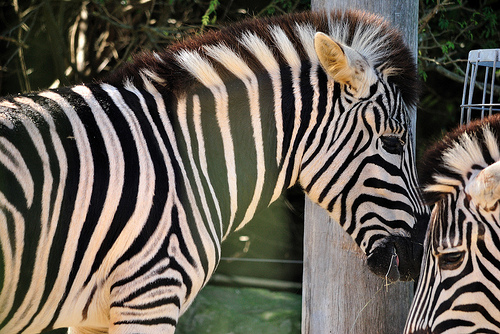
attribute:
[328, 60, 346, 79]
fur — yellow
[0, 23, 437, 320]
zebra — black, white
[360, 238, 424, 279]
mouth — black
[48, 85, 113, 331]
stripe — black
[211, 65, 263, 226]
stipe — black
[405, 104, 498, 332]
zebra — black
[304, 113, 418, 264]
stripes — narrow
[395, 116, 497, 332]
zebra — white, black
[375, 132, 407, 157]
eye — black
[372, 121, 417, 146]
eyes — black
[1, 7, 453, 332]
animal — white, black, striped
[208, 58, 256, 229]
stripe — black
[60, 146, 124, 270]
stripe — black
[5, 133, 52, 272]
stripe — black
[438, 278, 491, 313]
stripe — black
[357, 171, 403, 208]
stripe — black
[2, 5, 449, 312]
zebra — standing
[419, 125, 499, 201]
mane — brown, white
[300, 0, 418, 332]
pole — wooden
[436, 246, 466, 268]
eye — closed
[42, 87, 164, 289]
stripe — white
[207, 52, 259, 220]
stripe — black